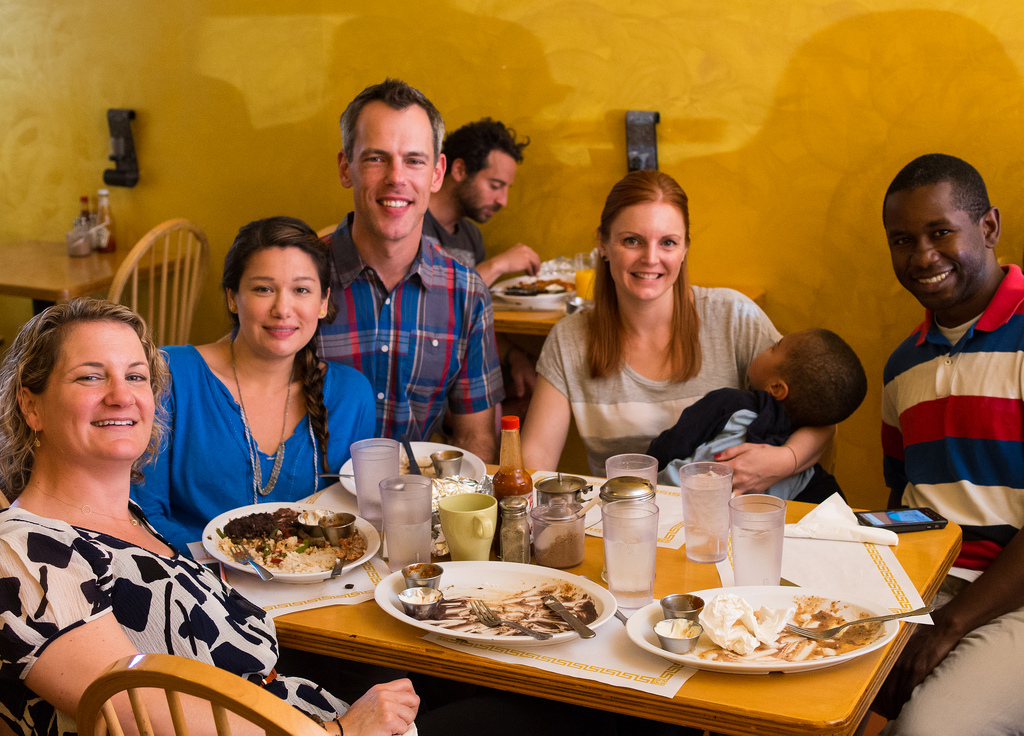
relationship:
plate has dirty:
[429, 585, 502, 618] [397, 563, 599, 637]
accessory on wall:
[93, 104, 153, 200] [733, 32, 863, 133]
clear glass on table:
[600, 499, 658, 609] [40, 237, 118, 275]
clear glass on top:
[600, 499, 658, 609] [428, 450, 802, 709]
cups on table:
[553, 447, 784, 588] [40, 237, 118, 275]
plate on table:
[429, 585, 502, 618] [40, 237, 118, 275]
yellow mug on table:
[440, 500, 503, 552] [40, 237, 118, 275]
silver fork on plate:
[501, 577, 592, 644] [429, 585, 502, 618]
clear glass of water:
[628, 516, 664, 597] [608, 482, 678, 596]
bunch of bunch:
[454, 486, 626, 559] [436, 493, 598, 569]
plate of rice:
[429, 585, 502, 618] [238, 517, 292, 556]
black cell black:
[865, 500, 937, 533] [852, 507, 947, 534]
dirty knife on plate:
[526, 583, 595, 662] [429, 585, 502, 618]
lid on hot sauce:
[499, 416, 519, 431] [476, 422, 544, 522]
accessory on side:
[102, 108, 140, 188] [134, 123, 252, 169]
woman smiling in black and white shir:
[593, 194, 749, 325] [551, 374, 662, 430]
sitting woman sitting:
[128, 215, 375, 567] [184, 354, 348, 426]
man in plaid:
[268, 127, 481, 216] [382, 324, 461, 395]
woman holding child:
[593, 194, 749, 325] [648, 330, 877, 454]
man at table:
[268, 127, 481, 216] [40, 237, 118, 275]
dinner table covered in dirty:
[314, 531, 704, 680] [397, 563, 599, 637]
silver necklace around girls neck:
[209, 361, 323, 497] [195, 336, 329, 524]